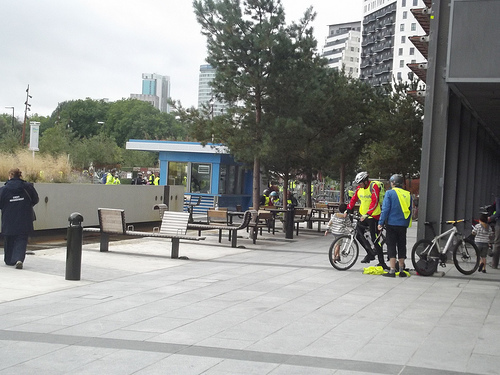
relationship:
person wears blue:
[0, 168, 39, 269] [9, 174, 36, 307]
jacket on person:
[347, 181, 382, 221] [339, 163, 390, 271]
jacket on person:
[377, 187, 407, 227] [369, 173, 418, 282]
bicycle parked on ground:
[411, 219, 481, 277] [4, 282, 500, 375]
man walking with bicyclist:
[343, 171, 388, 269] [328, 209, 390, 270]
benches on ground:
[80, 219, 203, 247] [4, 217, 498, 370]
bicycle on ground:
[407, 217, 488, 279] [4, 282, 500, 375]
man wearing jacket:
[345, 173, 391, 277] [347, 181, 382, 221]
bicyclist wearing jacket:
[340, 168, 391, 269] [342, 179, 386, 216]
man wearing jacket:
[377, 174, 412, 278] [375, 188, 417, 234]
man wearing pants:
[377, 174, 412, 278] [383, 223, 413, 261]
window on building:
[190, 159, 219, 197] [124, 128, 272, 228]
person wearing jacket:
[2, 166, 42, 276] [1, 176, 44, 238]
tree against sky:
[192, 2, 312, 230] [2, 4, 361, 127]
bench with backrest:
[78, 220, 210, 240] [97, 203, 127, 235]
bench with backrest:
[78, 220, 210, 240] [155, 209, 192, 233]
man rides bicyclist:
[343, 171, 388, 269] [328, 209, 390, 270]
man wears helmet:
[342, 169, 394, 279] [354, 169, 373, 187]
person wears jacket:
[0, 168, 39, 269] [378, 187, 413, 228]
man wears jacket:
[343, 171, 388, 269] [347, 181, 382, 221]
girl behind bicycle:
[467, 212, 497, 279] [411, 219, 481, 277]